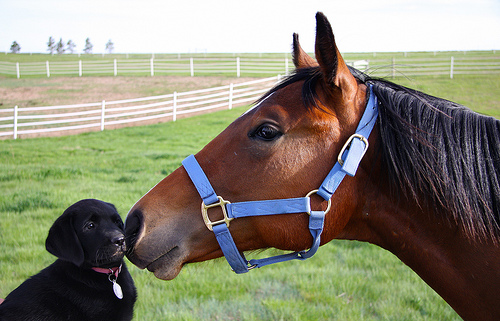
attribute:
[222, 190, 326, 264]
bridle — blue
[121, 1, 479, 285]
horse — brown, standing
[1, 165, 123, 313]
dog — black, sitting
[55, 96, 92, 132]
fence — wooden, white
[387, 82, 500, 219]
mane — black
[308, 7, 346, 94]
ear — perked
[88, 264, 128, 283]
collar — red, pink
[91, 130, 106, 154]
grass — green